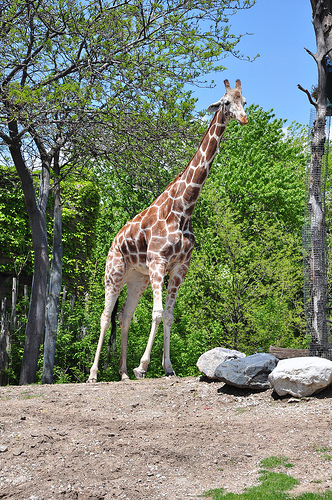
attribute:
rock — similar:
[268, 353, 329, 398]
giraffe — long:
[86, 76, 246, 382]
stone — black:
[221, 338, 278, 386]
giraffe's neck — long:
[147, 107, 230, 228]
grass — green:
[197, 455, 330, 498]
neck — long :
[154, 109, 232, 208]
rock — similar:
[212, 355, 277, 388]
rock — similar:
[196, 346, 244, 380]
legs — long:
[86, 241, 211, 390]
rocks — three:
[190, 338, 330, 402]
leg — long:
[131, 255, 164, 379]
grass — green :
[258, 456, 294, 467]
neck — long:
[173, 115, 222, 209]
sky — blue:
[220, 39, 307, 76]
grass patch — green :
[194, 453, 326, 498]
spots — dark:
[104, 104, 234, 311]